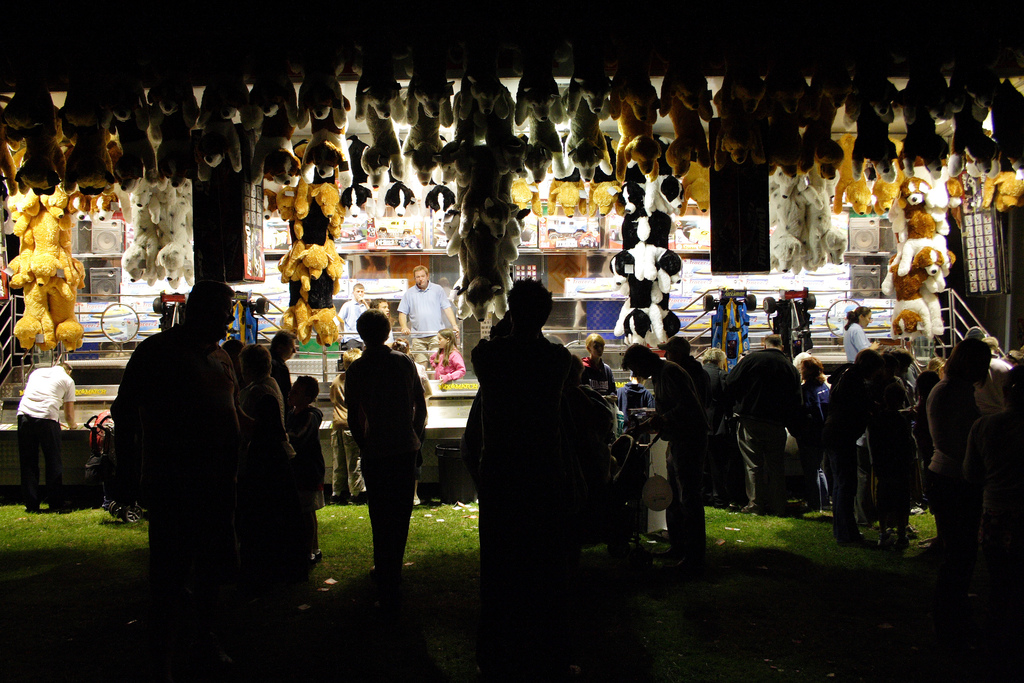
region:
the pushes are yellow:
[3, 175, 102, 363]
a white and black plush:
[606, 232, 684, 302]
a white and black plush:
[607, 173, 658, 218]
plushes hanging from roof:
[403, 63, 462, 225]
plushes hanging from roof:
[341, 68, 414, 223]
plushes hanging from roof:
[836, 72, 906, 229]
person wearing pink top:
[419, 319, 476, 409]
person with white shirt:
[2, 327, 89, 518]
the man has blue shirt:
[389, 249, 462, 336]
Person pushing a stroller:
[560, 397, 675, 554]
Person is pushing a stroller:
[561, 397, 661, 554]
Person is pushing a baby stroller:
[569, 396, 671, 558]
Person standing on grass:
[324, 299, 454, 593]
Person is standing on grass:
[332, 298, 434, 584]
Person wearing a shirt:
[5, 358, 82, 429]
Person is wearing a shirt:
[11, 364, 85, 425]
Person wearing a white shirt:
[8, 356, 82, 426]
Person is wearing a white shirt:
[14, 355, 79, 425]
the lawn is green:
[734, 509, 808, 554]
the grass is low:
[417, 501, 472, 553]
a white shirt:
[26, 364, 85, 421]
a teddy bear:
[282, 229, 340, 324]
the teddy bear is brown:
[285, 232, 347, 343]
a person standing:
[352, 320, 416, 574]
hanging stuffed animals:
[557, 81, 704, 164]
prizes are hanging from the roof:
[4, 77, 1019, 359]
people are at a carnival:
[8, 288, 1020, 620]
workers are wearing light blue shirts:
[340, 261, 458, 345]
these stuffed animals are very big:
[10, 140, 81, 346]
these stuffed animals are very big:
[266, 171, 353, 350]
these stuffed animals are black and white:
[602, 185, 692, 344]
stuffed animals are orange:
[17, 192, 100, 352]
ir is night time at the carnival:
[7, 5, 1022, 676]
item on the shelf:
[330, 214, 363, 247]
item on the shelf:
[381, 203, 408, 252]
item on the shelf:
[684, 224, 710, 253]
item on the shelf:
[826, 212, 891, 242]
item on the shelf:
[945, 176, 1012, 209]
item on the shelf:
[11, 218, 87, 289]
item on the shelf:
[355, 133, 414, 204]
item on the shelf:
[592, 143, 668, 217]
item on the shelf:
[283, 244, 340, 293]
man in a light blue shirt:
[397, 255, 465, 372]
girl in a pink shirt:
[422, 325, 470, 392]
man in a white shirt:
[18, 353, 91, 528]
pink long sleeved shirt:
[427, 341, 469, 386]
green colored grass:
[3, 499, 953, 573]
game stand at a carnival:
[3, 79, 1022, 500]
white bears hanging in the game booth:
[116, 178, 194, 299]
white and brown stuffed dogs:
[885, 155, 955, 336]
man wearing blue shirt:
[398, 265, 469, 341]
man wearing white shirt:
[19, 351, 74, 500]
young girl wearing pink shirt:
[424, 328, 464, 387]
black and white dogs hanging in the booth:
[606, 127, 689, 346]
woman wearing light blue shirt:
[841, 304, 877, 353]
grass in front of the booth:
[13, 475, 946, 665]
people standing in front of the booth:
[110, 257, 1008, 663]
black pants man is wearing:
[19, 418, 64, 501]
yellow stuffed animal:
[19, 190, 78, 299]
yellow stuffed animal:
[285, 217, 342, 307]